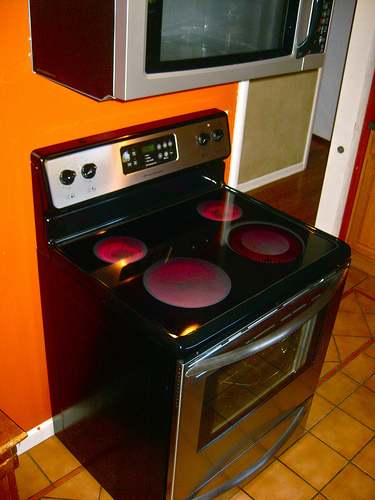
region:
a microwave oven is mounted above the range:
[20, 0, 338, 104]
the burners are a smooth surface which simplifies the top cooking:
[140, 251, 233, 309]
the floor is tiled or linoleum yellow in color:
[308, 430, 372, 498]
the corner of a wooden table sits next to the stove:
[1, 411, 29, 499]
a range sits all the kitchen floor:
[34, 107, 354, 498]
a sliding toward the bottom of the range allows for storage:
[172, 393, 318, 494]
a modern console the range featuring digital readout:
[112, 130, 182, 176]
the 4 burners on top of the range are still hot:
[91, 193, 309, 311]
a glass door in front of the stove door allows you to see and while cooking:
[201, 315, 311, 444]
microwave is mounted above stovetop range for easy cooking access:
[4, 2, 373, 108]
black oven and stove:
[31, 102, 357, 462]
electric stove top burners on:
[92, 189, 317, 344]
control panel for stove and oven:
[35, 106, 244, 216]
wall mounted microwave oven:
[29, 0, 341, 108]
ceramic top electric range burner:
[88, 231, 151, 269]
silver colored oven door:
[178, 281, 352, 485]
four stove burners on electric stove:
[85, 195, 312, 328]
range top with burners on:
[85, 192, 312, 321]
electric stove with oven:
[31, 103, 348, 497]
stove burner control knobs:
[54, 157, 102, 190]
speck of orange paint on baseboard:
[36, 424, 42, 432]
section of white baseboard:
[16, 415, 56, 457]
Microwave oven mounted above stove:
[26, 0, 335, 103]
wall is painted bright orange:
[0, 0, 239, 432]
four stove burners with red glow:
[94, 185, 307, 313]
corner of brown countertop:
[0, 400, 30, 498]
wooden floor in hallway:
[239, 132, 335, 226]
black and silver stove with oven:
[28, 107, 353, 499]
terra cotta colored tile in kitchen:
[8, 263, 374, 498]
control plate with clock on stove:
[118, 131, 181, 177]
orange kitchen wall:
[2, 97, 83, 130]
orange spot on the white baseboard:
[33, 425, 44, 436]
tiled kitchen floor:
[329, 382, 371, 499]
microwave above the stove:
[24, 0, 322, 96]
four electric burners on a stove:
[94, 198, 302, 310]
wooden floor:
[276, 183, 313, 216]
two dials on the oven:
[59, 160, 98, 190]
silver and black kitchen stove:
[58, 143, 307, 497]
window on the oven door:
[195, 287, 331, 454]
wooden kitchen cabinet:
[361, 176, 373, 262]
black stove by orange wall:
[39, 139, 339, 462]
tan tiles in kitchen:
[264, 419, 366, 499]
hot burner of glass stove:
[162, 259, 222, 305]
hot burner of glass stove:
[96, 226, 145, 269]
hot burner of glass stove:
[236, 230, 298, 276]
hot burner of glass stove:
[208, 188, 246, 228]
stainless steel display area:
[47, 146, 210, 195]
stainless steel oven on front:
[181, 326, 373, 459]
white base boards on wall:
[31, 413, 76, 451]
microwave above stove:
[98, 9, 341, 122]